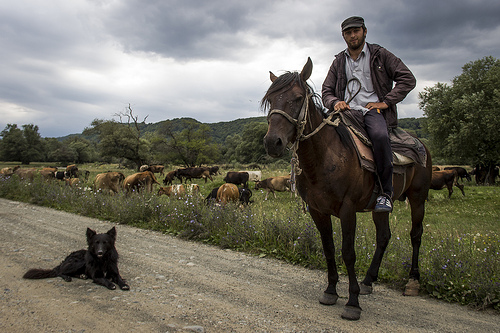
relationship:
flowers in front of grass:
[171, 211, 215, 235] [130, 188, 484, 301]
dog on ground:
[19, 220, 133, 294] [2, 197, 483, 330]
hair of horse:
[259, 67, 300, 113] [260, 55, 440, 325]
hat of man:
[336, 13, 368, 32] [317, 14, 418, 221]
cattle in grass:
[151, 182, 205, 204] [10, 158, 484, 304]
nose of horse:
[261, 129, 288, 157] [260, 55, 440, 325]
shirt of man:
[337, 45, 380, 120] [317, 14, 418, 221]